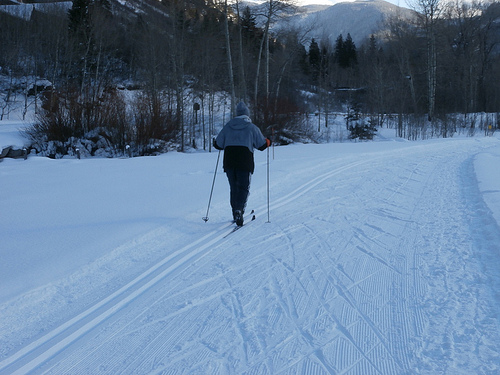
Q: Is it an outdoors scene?
A: Yes, it is outdoors.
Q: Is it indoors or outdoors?
A: It is outdoors.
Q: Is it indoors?
A: No, it is outdoors.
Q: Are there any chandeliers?
A: No, there are no chandeliers.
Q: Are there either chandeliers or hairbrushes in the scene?
A: No, there are no chandeliers or hairbrushes.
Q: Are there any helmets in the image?
A: No, there are no helmets.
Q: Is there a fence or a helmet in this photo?
A: No, there are no helmets or fences.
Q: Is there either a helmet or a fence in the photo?
A: No, there are no helmets or fences.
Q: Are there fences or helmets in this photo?
A: No, there are no helmets or fences.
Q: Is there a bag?
A: No, there are no bags.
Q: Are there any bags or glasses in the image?
A: No, there are no bags or glasses.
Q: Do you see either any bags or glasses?
A: No, there are no bags or glasses.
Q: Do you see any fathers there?
A: No, there are no fathers.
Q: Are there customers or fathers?
A: No, there are no fathers or customers.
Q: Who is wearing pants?
A: The man is wearing pants.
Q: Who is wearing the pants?
A: The man is wearing pants.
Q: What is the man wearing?
A: The man is wearing trousers.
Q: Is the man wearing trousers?
A: Yes, the man is wearing trousers.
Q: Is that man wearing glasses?
A: No, the man is wearing trousers.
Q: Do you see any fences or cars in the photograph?
A: No, there are no cars or fences.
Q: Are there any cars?
A: No, there are no cars.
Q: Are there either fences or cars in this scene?
A: No, there are no cars or fences.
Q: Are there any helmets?
A: No, there are no helmets.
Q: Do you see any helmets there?
A: No, there are no helmets.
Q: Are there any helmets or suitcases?
A: No, there are no helmets or suitcases.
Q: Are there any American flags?
A: No, there are no American flags.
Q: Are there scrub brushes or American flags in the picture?
A: No, there are no American flags or scrub brushes.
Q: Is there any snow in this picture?
A: Yes, there is snow.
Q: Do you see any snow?
A: Yes, there is snow.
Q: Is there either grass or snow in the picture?
A: Yes, there is snow.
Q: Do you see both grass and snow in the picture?
A: No, there is snow but no grass.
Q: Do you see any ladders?
A: No, there are no ladders.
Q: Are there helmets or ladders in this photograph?
A: No, there are no ladders or helmets.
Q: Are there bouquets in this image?
A: No, there are no bouquets.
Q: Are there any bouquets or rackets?
A: No, there are no bouquets or rackets.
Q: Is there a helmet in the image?
A: No, there are no helmets.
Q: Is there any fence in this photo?
A: No, there are no fences.